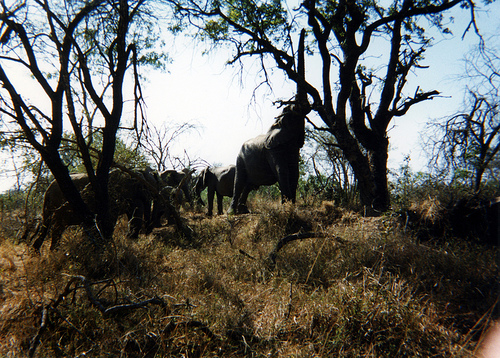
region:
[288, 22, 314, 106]
the trunk of the elephant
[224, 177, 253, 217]
the rear legs of the elephant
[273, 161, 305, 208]
the front legs of the elephant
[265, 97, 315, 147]
the head of an elephant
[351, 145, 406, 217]
the trunk of a tree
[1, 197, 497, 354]
yellow grass on the ground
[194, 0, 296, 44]
green leaves in the tree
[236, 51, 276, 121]
a branch in the tree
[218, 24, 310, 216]
a large elephant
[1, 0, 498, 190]
a gray sky overhead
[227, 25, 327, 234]
elephant reaching for tree leaves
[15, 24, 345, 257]
group of elephants standing between trees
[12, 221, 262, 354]
fallen tree branches on the ground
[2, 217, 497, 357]
patch of thick tall grass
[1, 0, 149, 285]
tree with broken branches and few leaves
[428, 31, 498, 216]
small tree protruding through the brush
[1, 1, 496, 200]
bright light blue sky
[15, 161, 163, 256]
elephant obscured by tree and brush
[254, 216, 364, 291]
broken tree branch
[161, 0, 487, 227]
large tree with leaves almost out of the reach of the elephant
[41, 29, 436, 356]
picture taken outdoors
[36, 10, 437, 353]
picture taken during the day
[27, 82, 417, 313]
a heard of elephants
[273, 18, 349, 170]
the trunk of an elephant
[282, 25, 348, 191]
the trunk is reaching upwards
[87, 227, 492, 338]
the grass is green and tan in color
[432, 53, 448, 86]
the sky has some clouds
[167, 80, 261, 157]
the sun is out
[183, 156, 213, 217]
elephant looks away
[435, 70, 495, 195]
the leaves are gone from the tree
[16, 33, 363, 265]
a herd of elephants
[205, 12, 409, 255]
the elephant uses its trunk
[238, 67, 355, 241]
the elephant reaches up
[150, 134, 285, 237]
elephants in the background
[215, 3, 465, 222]
the trees are bare within reach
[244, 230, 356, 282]
the underbrush is yellow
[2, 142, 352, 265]
the elephant on left has tusks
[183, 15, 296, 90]
the remaining leaves are green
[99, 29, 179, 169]
a broken tree branch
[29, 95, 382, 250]
the animals are elephants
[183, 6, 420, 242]
an elephant with trunk in air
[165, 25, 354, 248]
an elephant with head up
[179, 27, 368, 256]
an elephant standing outside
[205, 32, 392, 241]
an elephant standing in grass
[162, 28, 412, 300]
an elephant in field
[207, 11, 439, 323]
an elephant under tree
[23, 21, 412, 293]
a group of elephants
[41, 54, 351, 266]
a group of elephants outside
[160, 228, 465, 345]
a green grass field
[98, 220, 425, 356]
a field with green grass